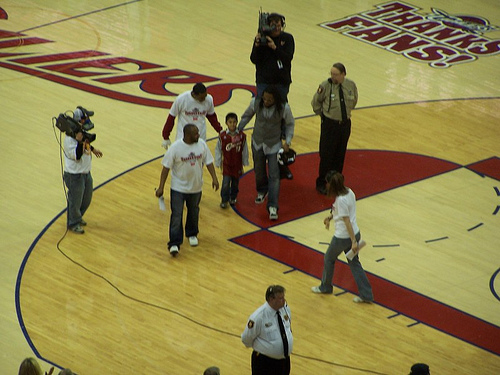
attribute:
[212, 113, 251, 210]
boy — walking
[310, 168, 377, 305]
woman — walking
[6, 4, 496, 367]
court — red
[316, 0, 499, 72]
writing — red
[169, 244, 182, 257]
shoe — white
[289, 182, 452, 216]
line — free throw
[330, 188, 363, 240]
shirt — white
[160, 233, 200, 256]
shoes — white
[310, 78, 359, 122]
shirt — brown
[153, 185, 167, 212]
paper — white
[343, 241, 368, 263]
paper — white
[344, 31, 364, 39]
frame — white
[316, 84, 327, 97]
emblem — gold, black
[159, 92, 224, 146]
shirt — white